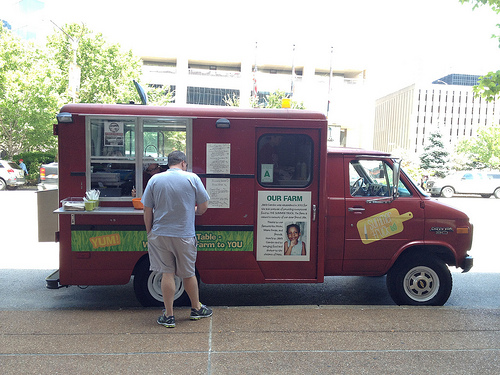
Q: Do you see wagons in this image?
A: No, there are no wagons.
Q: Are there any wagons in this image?
A: No, there are no wagons.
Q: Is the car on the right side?
A: Yes, the car is on the right of the image.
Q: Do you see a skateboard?
A: No, there are no skateboards.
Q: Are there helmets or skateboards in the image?
A: No, there are no skateboards or helmets.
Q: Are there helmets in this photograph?
A: No, there are no helmets.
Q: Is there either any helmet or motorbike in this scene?
A: No, there are no helmets or motorcycles.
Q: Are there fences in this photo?
A: No, there are no fences.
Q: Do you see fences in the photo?
A: No, there are no fences.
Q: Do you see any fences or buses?
A: No, there are no fences or buses.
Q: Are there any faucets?
A: No, there are no faucets.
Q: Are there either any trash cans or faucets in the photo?
A: No, there are no faucets or trash cans.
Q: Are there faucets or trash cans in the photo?
A: No, there are no faucets or trash cans.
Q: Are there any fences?
A: No, there are no fences.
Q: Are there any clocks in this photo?
A: No, there are no clocks.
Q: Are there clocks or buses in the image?
A: No, there are no clocks or buses.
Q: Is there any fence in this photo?
A: No, there are no fences.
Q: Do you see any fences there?
A: No, there are no fences.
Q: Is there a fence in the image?
A: No, there are no fences.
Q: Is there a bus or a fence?
A: No, there are no fences or buses.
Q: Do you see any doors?
A: Yes, there is a door.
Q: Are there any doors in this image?
A: Yes, there is a door.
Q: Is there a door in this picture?
A: Yes, there is a door.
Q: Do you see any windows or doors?
A: Yes, there is a door.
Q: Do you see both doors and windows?
A: Yes, there are both a door and a window.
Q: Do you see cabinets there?
A: No, there are no cabinets.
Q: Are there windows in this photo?
A: Yes, there is a window.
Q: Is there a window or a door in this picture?
A: Yes, there is a window.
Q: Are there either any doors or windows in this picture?
A: Yes, there is a window.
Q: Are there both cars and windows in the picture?
A: Yes, there are both a window and a car.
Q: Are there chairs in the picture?
A: No, there are no chairs.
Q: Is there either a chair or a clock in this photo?
A: No, there are no chairs or clocks.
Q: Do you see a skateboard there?
A: No, there are no skateboards.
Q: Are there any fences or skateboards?
A: No, there are no skateboards or fences.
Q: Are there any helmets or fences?
A: No, there are no fences or helmets.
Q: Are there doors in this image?
A: Yes, there is a door.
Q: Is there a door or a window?
A: Yes, there is a door.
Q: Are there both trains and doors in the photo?
A: No, there is a door but no trains.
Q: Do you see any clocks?
A: No, there are no clocks.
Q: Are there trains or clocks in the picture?
A: No, there are no clocks or trains.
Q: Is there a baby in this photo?
A: No, there are no babies.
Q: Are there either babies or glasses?
A: No, there are no babies or glasses.